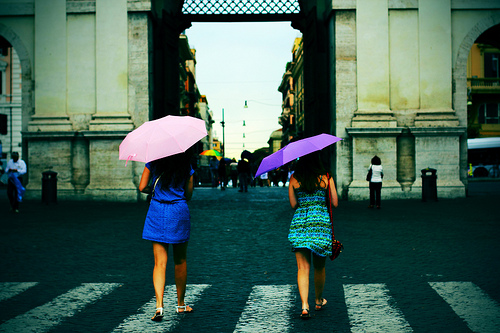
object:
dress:
[142, 161, 195, 243]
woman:
[365, 154, 384, 209]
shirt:
[367, 163, 383, 184]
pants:
[369, 182, 383, 206]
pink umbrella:
[118, 114, 208, 167]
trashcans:
[41, 171, 58, 204]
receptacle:
[420, 167, 439, 203]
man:
[4, 152, 27, 213]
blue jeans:
[9, 170, 25, 203]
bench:
[5, 172, 28, 186]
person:
[286, 153, 344, 317]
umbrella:
[254, 133, 342, 180]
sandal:
[299, 308, 310, 319]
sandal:
[314, 298, 328, 310]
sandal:
[175, 303, 187, 314]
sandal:
[152, 307, 163, 320]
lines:
[427, 281, 499, 333]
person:
[137, 153, 195, 320]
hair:
[148, 148, 191, 192]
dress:
[287, 174, 332, 257]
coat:
[4, 159, 26, 177]